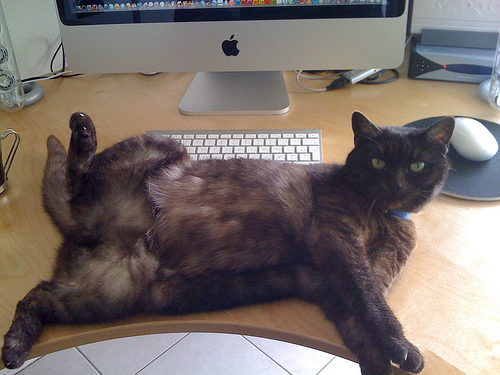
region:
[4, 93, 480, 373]
a cat laying on a desk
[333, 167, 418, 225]
a blue collar on a cat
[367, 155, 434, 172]
the eyes of a cat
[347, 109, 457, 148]
the ears of a cat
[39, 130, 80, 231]
the tail of a cat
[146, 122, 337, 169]
a keyboard on a desk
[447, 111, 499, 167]
a computer mouse on a pad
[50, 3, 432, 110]
a computer on a desk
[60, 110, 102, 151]
the paw of a cat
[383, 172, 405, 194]
the nose of a cat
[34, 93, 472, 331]
a cat laying down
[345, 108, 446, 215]
the head of a brown cat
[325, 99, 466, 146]
the ears of a brown cat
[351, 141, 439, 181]
the eyes of a brown cat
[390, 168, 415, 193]
the nose of a brown cat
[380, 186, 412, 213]
the mouth of a brown cat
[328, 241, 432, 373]
the front paws of a brown cat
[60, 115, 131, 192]
the foot of a brown cat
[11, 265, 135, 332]
the leg of a brown cat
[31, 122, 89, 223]
the tail of a brown cat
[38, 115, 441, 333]
a black cat wearing a collar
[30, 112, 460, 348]
a black cat wearing a blue collar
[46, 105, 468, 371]
a cat wearing a collar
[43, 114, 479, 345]
a cat wearing a blue collar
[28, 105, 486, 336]
a cat laying on a computer desk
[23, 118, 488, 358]
a black cat laying on a computer desk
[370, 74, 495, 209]
a white computer mouse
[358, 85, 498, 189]
a computer mouse on a desk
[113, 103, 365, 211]
a white and gray keyboard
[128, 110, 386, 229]
a keyboard on a computer desk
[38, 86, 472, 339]
a cat on the desk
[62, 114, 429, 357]
a brown and black cat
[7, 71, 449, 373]
this is a cat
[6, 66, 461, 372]
the cat is on a desk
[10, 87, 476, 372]
the cat is twisting its body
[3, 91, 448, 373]
a cat lying on a desktop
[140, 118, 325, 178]
this is a keyboard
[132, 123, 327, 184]
this is a wireless keyboard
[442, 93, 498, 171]
this is a computer mouse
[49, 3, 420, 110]
this is an Apple iMac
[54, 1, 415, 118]
this is a silver aluminum computer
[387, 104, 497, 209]
the mousepad is black